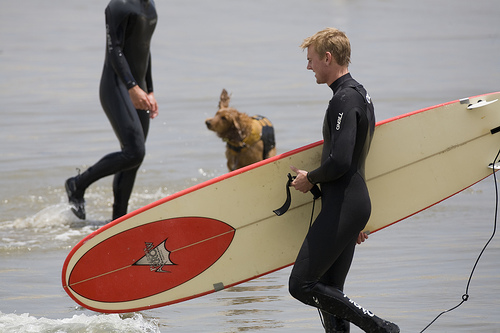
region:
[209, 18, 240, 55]
part of a water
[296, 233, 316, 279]
part of a thigh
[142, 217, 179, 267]
part of a board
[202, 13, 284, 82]
this is the water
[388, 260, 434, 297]
the water has ripples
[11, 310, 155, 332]
this is raised water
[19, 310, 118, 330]
the water is white in color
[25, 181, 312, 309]
this is a surfboard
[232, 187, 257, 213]
the surfboard is white in color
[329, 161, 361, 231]
the swimsuit is black in color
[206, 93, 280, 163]
this is a dog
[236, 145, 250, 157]
the fur is brown in color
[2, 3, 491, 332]
beach scene with dog and surfers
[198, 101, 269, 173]
wet irish setter drying off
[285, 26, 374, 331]
male surfer preparing to surf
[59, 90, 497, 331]
orange and creme colored surf board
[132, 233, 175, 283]
brand name logo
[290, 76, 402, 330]
black long sleeved wet suit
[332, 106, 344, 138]
logo in white lettering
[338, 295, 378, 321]
logo in white lettering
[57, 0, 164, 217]
female surfer in black wet suit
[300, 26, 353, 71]
full head of blond hair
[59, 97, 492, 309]
A surfboard in the hands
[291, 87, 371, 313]
Black surfwear in the photo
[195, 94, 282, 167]
A dog in the photo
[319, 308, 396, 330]
A dog in the photo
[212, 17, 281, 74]
Water in the photo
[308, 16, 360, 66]
Blonde hair in the photo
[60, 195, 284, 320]
A surfboard in the photo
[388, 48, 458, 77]
Water in the ocean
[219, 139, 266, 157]
A brace on the dog's neck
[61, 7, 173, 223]
A woman in the photo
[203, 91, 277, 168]
the dog standing in the water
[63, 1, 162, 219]
the man standing by the dog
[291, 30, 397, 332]
the man walking in the water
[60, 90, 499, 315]
the surfboard the man is holding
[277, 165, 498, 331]
the cord attached to the surfboard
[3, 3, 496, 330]
the water of the ocean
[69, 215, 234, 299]
the red spot of the logo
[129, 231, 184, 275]
the logo on the shirt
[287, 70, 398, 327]
the wetsuit the man is wearing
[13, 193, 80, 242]
the splashy part of the water